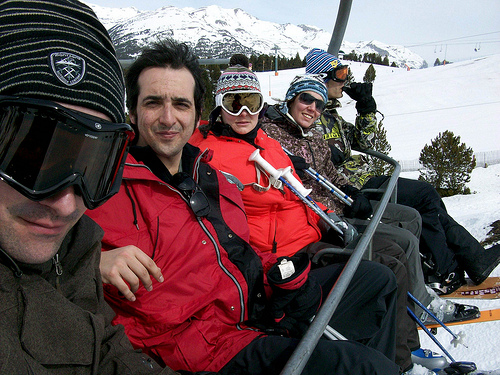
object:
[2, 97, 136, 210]
goggle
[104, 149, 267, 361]
jacket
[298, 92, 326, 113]
sunglasses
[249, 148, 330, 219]
pole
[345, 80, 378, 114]
glove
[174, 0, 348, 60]
mountain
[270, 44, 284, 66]
lift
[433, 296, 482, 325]
ski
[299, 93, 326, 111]
eyewear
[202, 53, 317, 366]
man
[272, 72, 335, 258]
woman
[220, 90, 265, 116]
eyeweare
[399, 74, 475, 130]
snow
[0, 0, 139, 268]
head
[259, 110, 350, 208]
jacket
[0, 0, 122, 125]
hat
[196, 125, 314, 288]
coat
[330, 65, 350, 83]
goggles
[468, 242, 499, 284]
boot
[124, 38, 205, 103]
hair